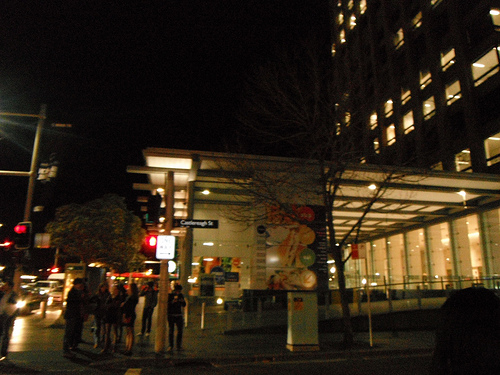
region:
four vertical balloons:
[294, 198, 322, 293]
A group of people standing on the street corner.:
[57, 269, 150, 369]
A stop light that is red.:
[7, 210, 37, 295]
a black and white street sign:
[169, 207, 221, 237]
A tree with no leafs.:
[209, 22, 459, 354]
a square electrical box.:
[286, 287, 323, 349]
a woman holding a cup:
[165, 277, 190, 352]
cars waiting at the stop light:
[7, 266, 67, 316]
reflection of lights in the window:
[182, 223, 232, 313]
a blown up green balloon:
[292, 240, 319, 271]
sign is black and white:
[162, 207, 234, 244]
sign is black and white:
[175, 210, 222, 237]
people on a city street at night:
[53, 101, 292, 357]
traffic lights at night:
[0, 200, 60, 263]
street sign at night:
[166, 199, 225, 249]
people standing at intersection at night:
[6, 290, 177, 368]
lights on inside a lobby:
[160, 172, 482, 321]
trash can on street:
[272, 282, 334, 357]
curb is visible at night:
[221, 338, 417, 368]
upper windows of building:
[323, 9, 488, 162]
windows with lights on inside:
[327, 12, 496, 168]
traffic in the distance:
[1, 261, 66, 312]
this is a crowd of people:
[65, 277, 185, 361]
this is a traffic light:
[8, 221, 33, 251]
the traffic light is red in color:
[12, 223, 27, 235]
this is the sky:
[17, 3, 187, 75]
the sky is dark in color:
[28, 5, 189, 71]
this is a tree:
[221, 43, 388, 348]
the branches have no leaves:
[214, 135, 302, 219]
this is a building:
[188, 150, 226, 323]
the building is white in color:
[397, 199, 435, 273]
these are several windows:
[436, 51, 496, 93]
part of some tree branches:
[291, 141, 358, 216]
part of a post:
[356, 285, 383, 344]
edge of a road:
[348, 342, 368, 357]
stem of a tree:
[327, 297, 364, 338]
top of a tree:
[89, 207, 130, 241]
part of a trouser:
[168, 319, 188, 349]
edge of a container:
[283, 302, 300, 338]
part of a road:
[393, 356, 407, 368]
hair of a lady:
[448, 323, 480, 361]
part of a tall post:
[13, 133, 50, 203]